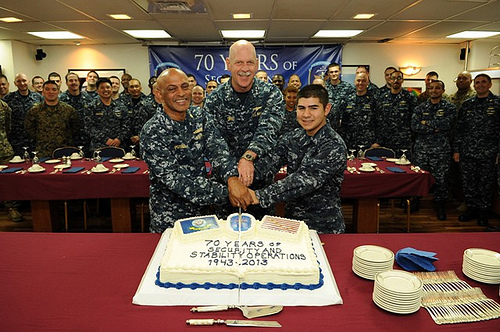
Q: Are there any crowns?
A: No, there are no crowns.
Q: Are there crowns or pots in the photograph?
A: No, there are no crowns or pots.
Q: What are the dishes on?
A: The dishes are on the table.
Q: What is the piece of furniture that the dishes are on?
A: The piece of furniture is a table.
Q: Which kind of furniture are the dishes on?
A: The dishes are on the table.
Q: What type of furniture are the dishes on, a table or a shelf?
A: The dishes are on a table.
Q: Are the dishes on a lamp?
A: No, the dishes are on the table.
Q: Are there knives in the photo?
A: Yes, there is a knife.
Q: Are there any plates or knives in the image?
A: Yes, there is a knife.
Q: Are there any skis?
A: No, there are no skis.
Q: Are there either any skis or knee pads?
A: No, there are no skis or knee pads.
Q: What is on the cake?
A: The icing is on the cake.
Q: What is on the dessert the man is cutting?
A: The icing is on the cake.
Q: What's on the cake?
A: The icing is on the cake.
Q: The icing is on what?
A: The icing is on the cake.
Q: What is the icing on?
A: The icing is on the cake.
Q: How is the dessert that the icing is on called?
A: The dessert is a cake.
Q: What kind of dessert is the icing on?
A: The icing is on the cake.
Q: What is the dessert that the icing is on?
A: The dessert is a cake.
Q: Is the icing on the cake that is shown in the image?
A: Yes, the icing is on the cake.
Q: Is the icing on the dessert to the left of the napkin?
A: Yes, the icing is on the cake.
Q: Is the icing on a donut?
A: No, the icing is on the cake.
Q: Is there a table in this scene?
A: Yes, there is a table.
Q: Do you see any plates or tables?
A: Yes, there is a table.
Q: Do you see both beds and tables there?
A: No, there is a table but no beds.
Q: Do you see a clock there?
A: No, there are no clocks.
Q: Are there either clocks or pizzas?
A: No, there are no clocks or pizzas.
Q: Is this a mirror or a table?
A: This is a table.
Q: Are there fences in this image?
A: No, there are no fences.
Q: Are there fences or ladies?
A: No, there are no fences or ladies.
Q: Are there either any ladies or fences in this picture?
A: No, there are no fences or ladies.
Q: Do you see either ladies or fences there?
A: No, there are no fences or ladies.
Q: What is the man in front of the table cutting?
A: The man is cutting the cake.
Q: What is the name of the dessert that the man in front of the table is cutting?
A: The dessert is a cake.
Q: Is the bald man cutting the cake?
A: Yes, the man is cutting the cake.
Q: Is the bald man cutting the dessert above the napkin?
A: Yes, the man is cutting the cake.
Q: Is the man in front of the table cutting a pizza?
A: No, the man is cutting the cake.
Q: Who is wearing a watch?
A: The man is wearing a watch.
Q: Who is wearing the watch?
A: The man is wearing a watch.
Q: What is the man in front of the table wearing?
A: The man is wearing a watch.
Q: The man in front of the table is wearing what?
A: The man is wearing a watch.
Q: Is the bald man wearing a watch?
A: Yes, the man is wearing a watch.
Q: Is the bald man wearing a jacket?
A: No, the man is wearing a watch.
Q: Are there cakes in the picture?
A: Yes, there is a cake.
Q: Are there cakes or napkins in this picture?
A: Yes, there is a cake.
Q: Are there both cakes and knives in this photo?
A: Yes, there are both a cake and a knife.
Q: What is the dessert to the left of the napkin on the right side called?
A: The dessert is a cake.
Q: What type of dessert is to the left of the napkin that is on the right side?
A: The dessert is a cake.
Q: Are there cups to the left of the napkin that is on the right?
A: No, there is a cake to the left of the napkin.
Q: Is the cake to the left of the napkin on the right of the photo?
A: Yes, the cake is to the left of the napkin.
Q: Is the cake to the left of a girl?
A: No, the cake is to the left of the napkin.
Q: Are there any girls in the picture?
A: No, there are no girls.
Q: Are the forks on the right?
A: Yes, the forks are on the right of the image.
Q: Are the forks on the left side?
A: No, the forks are on the right of the image.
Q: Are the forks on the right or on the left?
A: The forks are on the right of the image.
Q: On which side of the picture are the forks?
A: The forks are on the right of the image.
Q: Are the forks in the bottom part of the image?
A: Yes, the forks are in the bottom of the image.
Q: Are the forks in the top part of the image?
A: No, the forks are in the bottom of the image.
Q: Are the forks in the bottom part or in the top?
A: The forks are in the bottom of the image.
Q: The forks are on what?
A: The forks are on the table.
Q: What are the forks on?
A: The forks are on the table.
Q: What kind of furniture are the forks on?
A: The forks are on the table.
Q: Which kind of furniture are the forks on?
A: The forks are on the table.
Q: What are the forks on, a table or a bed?
A: The forks are on a table.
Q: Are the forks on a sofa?
A: No, the forks are on the table.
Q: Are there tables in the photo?
A: Yes, there is a table.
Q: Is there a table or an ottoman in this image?
A: Yes, there is a table.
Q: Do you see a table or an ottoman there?
A: Yes, there is a table.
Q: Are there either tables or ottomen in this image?
A: Yes, there is a table.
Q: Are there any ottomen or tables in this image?
A: Yes, there is a table.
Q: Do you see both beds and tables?
A: No, there is a table but no beds.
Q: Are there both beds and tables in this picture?
A: No, there is a table but no beds.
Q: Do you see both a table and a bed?
A: No, there is a table but no beds.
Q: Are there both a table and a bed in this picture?
A: No, there is a table but no beds.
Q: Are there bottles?
A: No, there are no bottles.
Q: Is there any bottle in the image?
A: No, there are no bottles.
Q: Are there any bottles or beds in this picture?
A: No, there are no bottles or beds.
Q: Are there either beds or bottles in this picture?
A: No, there are no bottles or beds.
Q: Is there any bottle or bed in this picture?
A: No, there are no bottles or beds.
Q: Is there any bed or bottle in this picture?
A: No, there are no bottles or beds.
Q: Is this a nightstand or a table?
A: This is a table.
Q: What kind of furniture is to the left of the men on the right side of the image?
A: The piece of furniture is a table.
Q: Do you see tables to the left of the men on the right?
A: Yes, there is a table to the left of the men.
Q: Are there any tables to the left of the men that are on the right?
A: Yes, there is a table to the left of the men.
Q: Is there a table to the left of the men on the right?
A: Yes, there is a table to the left of the men.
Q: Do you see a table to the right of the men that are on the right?
A: No, the table is to the left of the men.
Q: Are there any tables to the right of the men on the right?
A: No, the table is to the left of the men.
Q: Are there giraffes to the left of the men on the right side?
A: No, there is a table to the left of the men.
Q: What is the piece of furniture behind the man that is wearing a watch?
A: The piece of furniture is a table.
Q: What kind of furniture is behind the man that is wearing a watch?
A: The piece of furniture is a table.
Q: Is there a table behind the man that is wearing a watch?
A: Yes, there is a table behind the man.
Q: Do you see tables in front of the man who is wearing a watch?
A: No, the table is behind the man.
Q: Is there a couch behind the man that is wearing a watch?
A: No, there is a table behind the man.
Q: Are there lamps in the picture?
A: No, there are no lamps.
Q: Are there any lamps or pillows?
A: No, there are no lamps or pillows.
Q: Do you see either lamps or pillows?
A: No, there are no lamps or pillows.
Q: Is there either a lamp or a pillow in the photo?
A: No, there are no lamps or pillows.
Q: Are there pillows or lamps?
A: No, there are no lamps or pillows.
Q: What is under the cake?
A: The napkin is under the cake.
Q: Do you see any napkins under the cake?
A: Yes, there is a napkin under the cake.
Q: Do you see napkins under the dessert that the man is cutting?
A: Yes, there is a napkin under the cake.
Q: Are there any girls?
A: No, there are no girls.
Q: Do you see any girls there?
A: No, there are no girls.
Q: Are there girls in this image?
A: No, there are no girls.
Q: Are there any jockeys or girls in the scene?
A: No, there are no girls or jockeys.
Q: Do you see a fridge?
A: No, there are no refrigerators.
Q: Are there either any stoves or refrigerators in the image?
A: No, there are no refrigerators or stoves.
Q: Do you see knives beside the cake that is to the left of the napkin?
A: Yes, there are knives beside the cake.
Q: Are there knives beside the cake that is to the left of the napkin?
A: Yes, there are knives beside the cake.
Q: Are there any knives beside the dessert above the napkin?
A: Yes, there are knives beside the cake.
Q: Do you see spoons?
A: No, there are no spoons.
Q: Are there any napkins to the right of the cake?
A: Yes, there is a napkin to the right of the cake.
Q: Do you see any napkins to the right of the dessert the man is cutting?
A: Yes, there is a napkin to the right of the cake.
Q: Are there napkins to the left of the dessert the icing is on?
A: No, the napkin is to the right of the cake.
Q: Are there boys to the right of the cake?
A: No, there is a napkin to the right of the cake.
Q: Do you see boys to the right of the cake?
A: No, there is a napkin to the right of the cake.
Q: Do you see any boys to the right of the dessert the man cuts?
A: No, there is a napkin to the right of the cake.